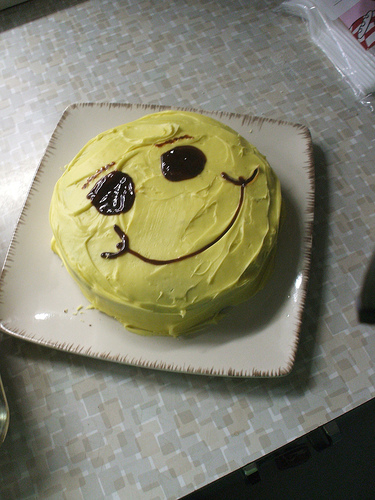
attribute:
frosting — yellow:
[48, 107, 284, 340]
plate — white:
[38, 229, 46, 342]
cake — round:
[29, 94, 304, 345]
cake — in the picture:
[45, 129, 202, 268]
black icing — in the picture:
[153, 156, 195, 179]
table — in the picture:
[2, 2, 371, 499]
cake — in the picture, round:
[43, 106, 290, 342]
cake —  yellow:
[89, 142, 265, 249]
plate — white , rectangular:
[0, 91, 318, 380]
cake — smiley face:
[13, 95, 374, 405]